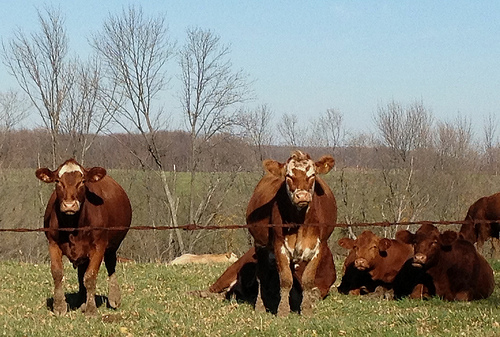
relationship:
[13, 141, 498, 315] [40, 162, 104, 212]
cow has head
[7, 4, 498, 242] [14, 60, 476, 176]
trees on background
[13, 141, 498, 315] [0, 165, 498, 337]
cow in field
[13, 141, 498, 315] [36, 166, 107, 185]
cow has ears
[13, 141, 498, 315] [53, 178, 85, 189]
cow has eye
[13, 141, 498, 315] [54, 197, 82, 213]
cow has nose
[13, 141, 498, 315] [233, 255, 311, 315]
cow casting shadow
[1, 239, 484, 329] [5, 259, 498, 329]
field filled with grass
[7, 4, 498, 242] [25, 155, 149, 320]
trees near cow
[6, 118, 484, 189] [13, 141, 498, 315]
land distant from cow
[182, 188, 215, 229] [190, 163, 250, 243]
twig by branch